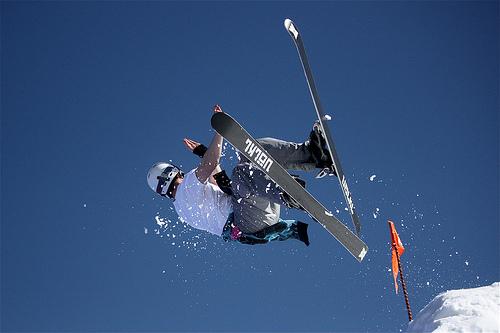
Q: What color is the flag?
A: Orange.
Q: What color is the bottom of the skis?
A: Black.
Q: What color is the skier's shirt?
A: White.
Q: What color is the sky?
A: Blue.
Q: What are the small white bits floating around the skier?
A: Snow.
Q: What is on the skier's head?
A: A helmet.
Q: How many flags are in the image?
A: One.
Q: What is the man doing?
A: Skiing.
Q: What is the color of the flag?
A: Orange.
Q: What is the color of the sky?
A: Blue.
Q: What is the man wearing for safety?
A: Helmet.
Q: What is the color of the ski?
A: Black.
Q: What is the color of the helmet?
A: White.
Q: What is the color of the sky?
A: Blue.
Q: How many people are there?
A: 1.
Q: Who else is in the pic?
A: Npo one.